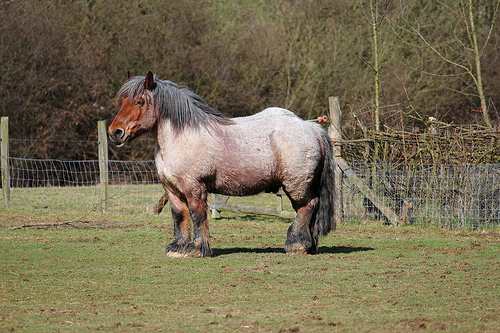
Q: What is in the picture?
A: A horse.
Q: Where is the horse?
A: A pasture.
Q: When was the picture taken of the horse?
A: Daytime.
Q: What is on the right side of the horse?
A: A fence.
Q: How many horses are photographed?
A: One.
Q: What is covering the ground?
A: Grass.